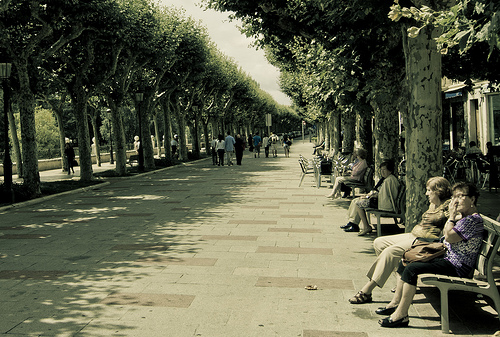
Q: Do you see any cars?
A: No, there are no cars.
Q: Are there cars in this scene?
A: No, there are no cars.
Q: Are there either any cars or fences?
A: No, there are no cars or fences.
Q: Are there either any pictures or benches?
A: Yes, there is a bench.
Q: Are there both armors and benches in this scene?
A: No, there is a bench but no armors.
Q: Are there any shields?
A: No, there are no shields.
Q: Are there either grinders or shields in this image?
A: No, there are no shields or grinders.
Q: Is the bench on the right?
A: Yes, the bench is on the right of the image.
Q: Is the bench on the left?
A: No, the bench is on the right of the image.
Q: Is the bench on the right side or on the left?
A: The bench is on the right of the image.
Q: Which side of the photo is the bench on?
A: The bench is on the right of the image.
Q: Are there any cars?
A: No, there are no cars.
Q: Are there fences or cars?
A: No, there are no cars or fences.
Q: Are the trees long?
A: Yes, the trees are long.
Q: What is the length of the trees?
A: The trees are long.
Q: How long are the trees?
A: The trees are long.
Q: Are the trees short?
A: No, the trees are long.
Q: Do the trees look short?
A: No, the trees are long.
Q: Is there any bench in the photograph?
A: Yes, there is a bench.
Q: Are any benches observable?
A: Yes, there is a bench.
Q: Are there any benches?
A: Yes, there is a bench.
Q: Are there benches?
A: Yes, there is a bench.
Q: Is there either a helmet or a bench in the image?
A: Yes, there is a bench.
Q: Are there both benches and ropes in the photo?
A: No, there is a bench but no ropes.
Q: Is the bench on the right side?
A: Yes, the bench is on the right of the image.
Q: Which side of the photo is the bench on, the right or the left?
A: The bench is on the right of the image.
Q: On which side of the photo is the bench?
A: The bench is on the right of the image.